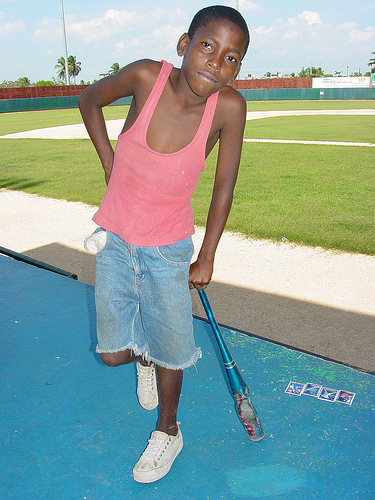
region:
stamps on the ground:
[281, 371, 358, 406]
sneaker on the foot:
[121, 423, 177, 485]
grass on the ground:
[288, 233, 344, 239]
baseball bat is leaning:
[190, 285, 273, 446]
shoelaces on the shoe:
[134, 437, 159, 469]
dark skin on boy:
[144, 393, 186, 433]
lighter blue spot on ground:
[227, 451, 255, 496]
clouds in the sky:
[280, 8, 337, 46]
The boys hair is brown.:
[173, 3, 251, 96]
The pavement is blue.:
[11, 413, 92, 488]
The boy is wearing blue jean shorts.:
[77, 222, 202, 365]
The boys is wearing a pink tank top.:
[90, 3, 260, 255]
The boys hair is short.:
[174, 4, 250, 98]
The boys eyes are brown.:
[199, 38, 238, 62]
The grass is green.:
[283, 163, 366, 228]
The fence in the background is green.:
[277, 89, 317, 100]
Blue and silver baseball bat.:
[186, 248, 289, 449]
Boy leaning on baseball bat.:
[110, 5, 268, 479]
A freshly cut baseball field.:
[9, 90, 374, 268]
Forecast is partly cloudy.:
[34, 7, 364, 68]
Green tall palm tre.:
[47, 52, 82, 90]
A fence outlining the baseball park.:
[11, 78, 366, 108]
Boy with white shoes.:
[93, 335, 191, 483]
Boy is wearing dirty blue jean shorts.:
[83, 212, 209, 378]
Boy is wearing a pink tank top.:
[79, 64, 235, 244]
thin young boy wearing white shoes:
[75, 5, 252, 483]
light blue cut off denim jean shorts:
[83, 225, 201, 371]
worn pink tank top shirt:
[90, 57, 221, 247]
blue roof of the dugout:
[1, 245, 373, 498]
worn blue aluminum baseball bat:
[199, 287, 265, 442]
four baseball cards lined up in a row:
[284, 379, 356, 406]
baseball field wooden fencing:
[0, 72, 373, 113]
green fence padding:
[1, 86, 373, 113]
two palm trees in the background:
[55, 53, 82, 84]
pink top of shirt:
[119, 85, 214, 237]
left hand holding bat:
[186, 266, 278, 451]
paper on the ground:
[276, 377, 374, 424]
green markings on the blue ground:
[224, 352, 337, 379]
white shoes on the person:
[128, 431, 179, 485]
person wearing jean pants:
[94, 240, 214, 373]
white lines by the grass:
[232, 243, 366, 298]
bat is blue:
[195, 289, 266, 439]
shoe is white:
[131, 420, 183, 484]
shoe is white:
[134, 358, 159, 411]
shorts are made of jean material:
[82, 224, 202, 370]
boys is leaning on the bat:
[75, 4, 267, 480]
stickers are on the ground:
[281, 379, 354, 404]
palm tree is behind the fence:
[53, 54, 81, 82]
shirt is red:
[92, 59, 219, 248]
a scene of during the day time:
[4, 8, 374, 496]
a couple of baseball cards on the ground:
[277, 369, 360, 423]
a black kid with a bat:
[66, 1, 280, 494]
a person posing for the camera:
[61, 2, 276, 490]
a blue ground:
[4, 255, 374, 493]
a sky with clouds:
[8, 3, 372, 70]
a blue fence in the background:
[2, 81, 372, 115]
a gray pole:
[51, 0, 69, 90]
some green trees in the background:
[2, 47, 372, 99]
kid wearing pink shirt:
[75, 1, 249, 484]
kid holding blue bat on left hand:
[75, 4, 244, 480]